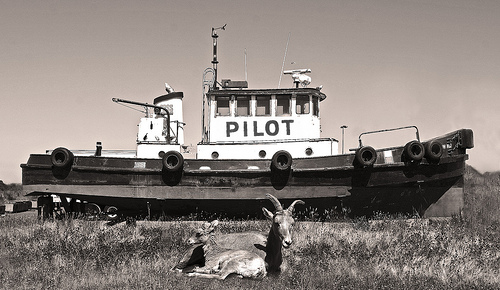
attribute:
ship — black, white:
[21, 23, 476, 225]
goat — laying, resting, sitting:
[170, 188, 306, 274]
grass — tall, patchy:
[3, 215, 498, 288]